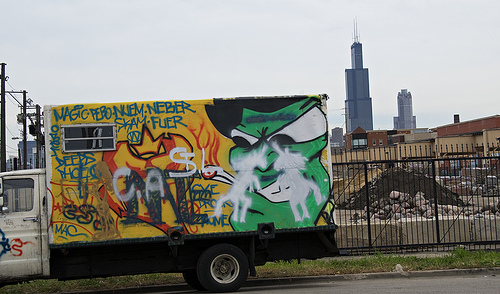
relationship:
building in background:
[344, 18, 374, 130] [1, 1, 498, 172]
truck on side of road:
[0, 94, 340, 292] [82, 266, 499, 293]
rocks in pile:
[391, 190, 399, 199] [363, 191, 460, 220]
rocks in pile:
[415, 200, 425, 205] [363, 191, 460, 220]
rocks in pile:
[422, 210, 434, 219] [363, 191, 460, 220]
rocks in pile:
[445, 205, 451, 213] [363, 191, 460, 220]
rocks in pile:
[377, 212, 387, 219] [363, 191, 460, 220]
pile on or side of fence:
[363, 191, 460, 220] [331, 149, 499, 255]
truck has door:
[0, 94, 340, 292] [0, 173, 42, 277]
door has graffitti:
[0, 173, 42, 277] [0, 230, 35, 258]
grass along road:
[2, 248, 498, 294] [82, 266, 499, 293]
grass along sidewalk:
[2, 248, 498, 294] [286, 252, 498, 262]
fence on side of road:
[331, 149, 499, 255] [82, 266, 499, 293]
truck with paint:
[0, 94, 340, 292] [0, 95, 335, 260]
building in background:
[392, 90, 416, 130] [1, 1, 498, 172]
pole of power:
[23, 91, 28, 170] [29, 123, 38, 135]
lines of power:
[3, 89, 45, 131] [29, 123, 38, 135]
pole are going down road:
[23, 91, 28, 170] [82, 266, 499, 293]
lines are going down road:
[3, 89, 45, 131] [82, 266, 499, 293]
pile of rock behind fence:
[357, 192, 497, 217] [331, 149, 499, 255]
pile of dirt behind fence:
[337, 165, 470, 209] [331, 149, 499, 255]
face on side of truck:
[230, 96, 327, 231] [0, 94, 340, 292]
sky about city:
[3, 0, 499, 159] [0, 1, 498, 294]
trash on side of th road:
[396, 264, 410, 278] [82, 266, 499, 293]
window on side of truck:
[61, 122, 117, 155] [0, 94, 340, 292]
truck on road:
[0, 94, 340, 292] [82, 266, 499, 293]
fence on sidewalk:
[331, 149, 499, 255] [286, 252, 498, 262]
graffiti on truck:
[0, 95, 336, 257] [0, 94, 340, 292]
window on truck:
[61, 122, 117, 155] [0, 94, 340, 292]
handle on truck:
[23, 216, 38, 224] [0, 94, 340, 292]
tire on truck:
[197, 243, 248, 292] [0, 94, 340, 292]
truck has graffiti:
[0, 94, 340, 292] [0, 95, 336, 257]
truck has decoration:
[0, 94, 340, 292] [47, 94, 337, 247]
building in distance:
[344, 18, 374, 130] [1, 1, 498, 172]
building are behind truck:
[344, 18, 374, 130] [0, 94, 340, 292]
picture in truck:
[230, 96, 327, 231] [0, 94, 340, 292]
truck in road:
[0, 94, 340, 292] [82, 266, 499, 293]